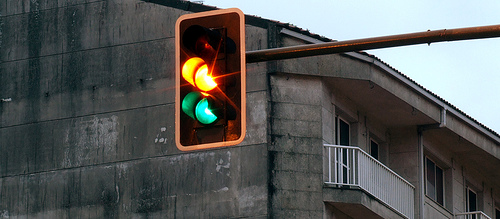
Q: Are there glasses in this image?
A: No, there are no glasses.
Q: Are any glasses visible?
A: No, there are no glasses.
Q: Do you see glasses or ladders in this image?
A: No, there are no glasses or ladders.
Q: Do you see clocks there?
A: No, there are no clocks.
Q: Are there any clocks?
A: No, there are no clocks.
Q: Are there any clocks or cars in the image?
A: No, there are no clocks or cars.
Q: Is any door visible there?
A: Yes, there are doors.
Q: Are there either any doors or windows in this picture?
A: Yes, there are doors.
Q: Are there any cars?
A: No, there are no cars.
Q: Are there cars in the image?
A: No, there are no cars.